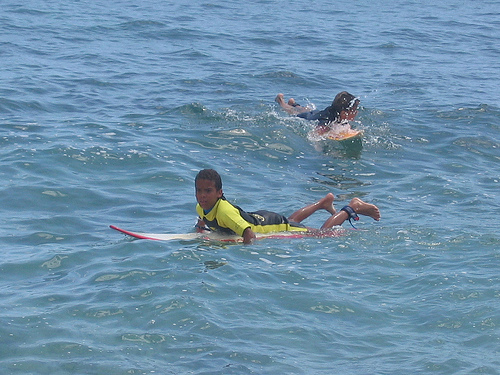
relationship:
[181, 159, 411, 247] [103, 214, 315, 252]
boy on surfboard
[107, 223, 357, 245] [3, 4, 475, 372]
surfboard on water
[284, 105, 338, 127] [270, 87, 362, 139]
clothing on boy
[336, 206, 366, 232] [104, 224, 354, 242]
ankle cable to surfboard